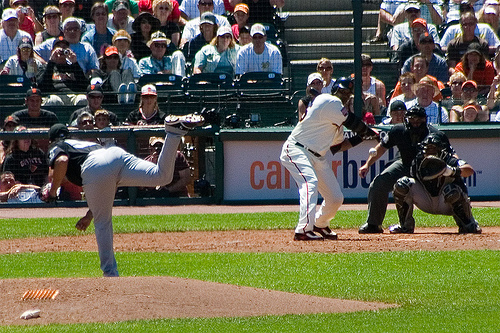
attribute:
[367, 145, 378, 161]
ball — in air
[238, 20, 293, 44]
cap — white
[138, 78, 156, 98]
cap — red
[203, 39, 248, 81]
top — light blue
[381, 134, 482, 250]
catcher — kneeling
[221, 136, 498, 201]
ad — white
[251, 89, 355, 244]
uniform — white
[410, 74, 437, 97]
hat — yellow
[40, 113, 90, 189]
jersey — black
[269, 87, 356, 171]
shirt — white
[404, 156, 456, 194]
mitt — open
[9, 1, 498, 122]
fans — watching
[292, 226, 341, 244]
shoes — black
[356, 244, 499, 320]
field — green, beautiful, nice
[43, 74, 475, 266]
players — playing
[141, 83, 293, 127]
seats — empty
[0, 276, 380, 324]
mound — dirt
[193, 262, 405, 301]
grass — cut, green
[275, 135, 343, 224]
pants — white